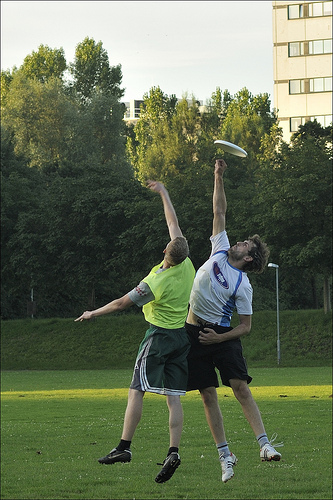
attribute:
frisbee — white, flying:
[202, 125, 252, 179]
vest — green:
[145, 264, 191, 332]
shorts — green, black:
[103, 297, 263, 440]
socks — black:
[114, 430, 188, 463]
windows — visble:
[280, 31, 332, 61]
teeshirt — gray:
[195, 233, 249, 335]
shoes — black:
[87, 438, 284, 492]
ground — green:
[27, 401, 99, 445]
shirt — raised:
[186, 224, 255, 329]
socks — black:
[115, 436, 180, 452]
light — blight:
[0, 382, 330, 400]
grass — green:
[3, 424, 332, 499]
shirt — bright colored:
[136, 255, 197, 330]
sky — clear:
[3, 5, 274, 92]